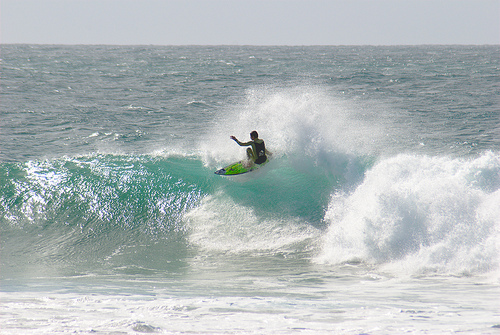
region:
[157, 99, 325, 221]
A person is surfing in an ocean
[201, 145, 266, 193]
The surfboard is neon green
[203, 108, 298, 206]
Person is riding a wave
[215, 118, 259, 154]
Person has their hand in the air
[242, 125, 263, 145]
Person has short hair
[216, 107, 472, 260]
A large ocean wave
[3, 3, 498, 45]
The sky is clear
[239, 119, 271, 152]
Person is looking away from the camera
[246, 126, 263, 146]
A side view of a person's head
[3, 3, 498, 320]
Photo was taken in the daytime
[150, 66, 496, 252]
a man surfing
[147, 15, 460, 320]
a man surfing on water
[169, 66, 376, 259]
a man surfing during the day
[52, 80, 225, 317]
a body of water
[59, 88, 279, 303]
a body of wavy water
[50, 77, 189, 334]
a body of water with waves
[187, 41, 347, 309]
a surfer riding a wave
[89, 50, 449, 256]
a man riding a wave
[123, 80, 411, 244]
a man on a surfboard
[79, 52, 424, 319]
a man on a wave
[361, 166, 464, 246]
the wave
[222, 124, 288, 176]
person on a surfboard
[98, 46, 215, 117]
the ocean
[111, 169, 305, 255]
a big wave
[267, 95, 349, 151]
a big splash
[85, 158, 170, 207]
the wave is blue and green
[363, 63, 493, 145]
the water is blue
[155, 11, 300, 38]
blue sky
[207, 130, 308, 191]
person riding a wave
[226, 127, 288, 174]
the persons hand is up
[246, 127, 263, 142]
the head of a man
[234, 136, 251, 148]
the arm of a man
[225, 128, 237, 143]
the hand of a man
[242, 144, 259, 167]
the leg of a man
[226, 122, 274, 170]
a man on the surfboard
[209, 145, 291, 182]
a green surfboard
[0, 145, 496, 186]
the crest of a wave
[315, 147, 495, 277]
white foaming water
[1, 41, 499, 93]
calm water behind the wave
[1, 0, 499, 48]
a gray sky overhead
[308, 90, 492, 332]
clear big ocean waves